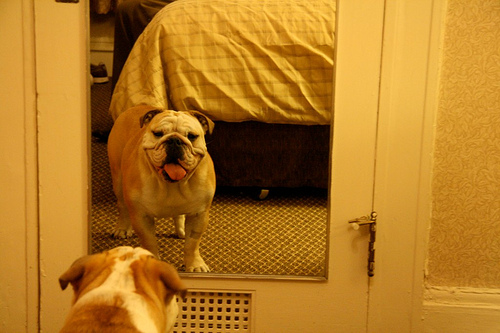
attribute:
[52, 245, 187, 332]
dog — brown, white, chubby, bulldog, smiling, bull dog, large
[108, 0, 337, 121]
comforter — checkered, yellow, white, patterned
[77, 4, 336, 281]
mirror — mounted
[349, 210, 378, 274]
door hinge — mounted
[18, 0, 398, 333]
door — white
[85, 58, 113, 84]
shoes — pair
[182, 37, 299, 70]
lines — light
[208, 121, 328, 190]
bottom — dark brown, wooden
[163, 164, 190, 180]
tongue — hanging out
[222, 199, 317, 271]
carpet — patterned, checkered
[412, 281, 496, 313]
moulding — white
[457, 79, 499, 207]
wallpaper — patterned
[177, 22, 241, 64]
pattern — square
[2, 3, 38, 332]
doorframe — white